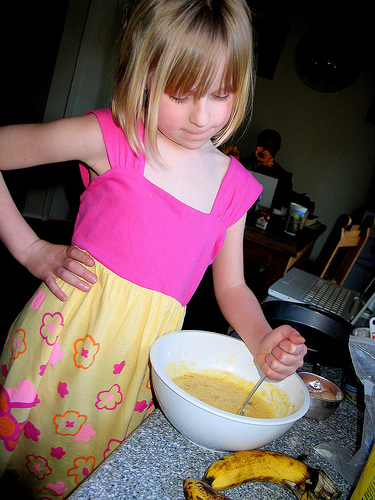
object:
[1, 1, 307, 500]
girl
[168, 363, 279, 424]
food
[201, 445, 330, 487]
food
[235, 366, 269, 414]
utensil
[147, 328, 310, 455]
bowl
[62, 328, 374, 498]
counter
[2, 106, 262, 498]
dress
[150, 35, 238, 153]
face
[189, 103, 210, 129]
nose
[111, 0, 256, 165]
hair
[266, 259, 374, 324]
laptop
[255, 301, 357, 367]
pan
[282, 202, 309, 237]
cup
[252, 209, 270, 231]
cigarettes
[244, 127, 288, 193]
person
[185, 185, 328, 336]
desk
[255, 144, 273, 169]
flowers